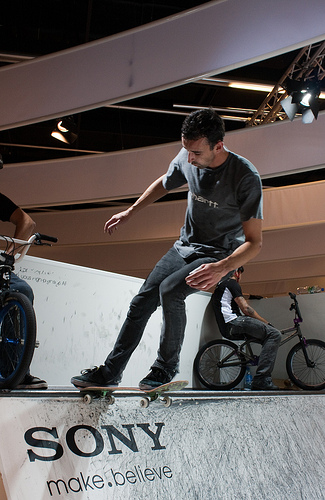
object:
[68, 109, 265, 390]
man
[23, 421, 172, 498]
advertisement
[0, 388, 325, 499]
ramp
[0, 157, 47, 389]
man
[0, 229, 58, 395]
bicycle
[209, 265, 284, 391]
man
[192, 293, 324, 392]
bicycle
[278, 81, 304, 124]
lighting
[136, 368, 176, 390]
foot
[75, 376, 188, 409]
skateboard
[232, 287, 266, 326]
arm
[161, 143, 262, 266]
shirt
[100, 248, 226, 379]
jeans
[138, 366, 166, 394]
shoe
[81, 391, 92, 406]
wheels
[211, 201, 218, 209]
lettering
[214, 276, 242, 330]
shirt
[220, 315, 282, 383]
jeans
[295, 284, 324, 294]
bottle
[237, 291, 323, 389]
wall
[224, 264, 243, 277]
helmet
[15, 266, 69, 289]
grafitti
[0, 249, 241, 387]
wall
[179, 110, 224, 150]
hair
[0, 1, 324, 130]
beam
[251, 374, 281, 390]
shoe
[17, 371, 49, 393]
shoe